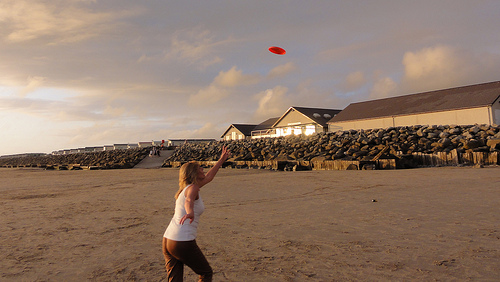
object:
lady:
[151, 147, 228, 280]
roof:
[330, 82, 497, 120]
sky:
[7, 1, 282, 111]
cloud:
[190, 67, 246, 112]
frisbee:
[268, 47, 286, 55]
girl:
[162, 142, 232, 282]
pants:
[160, 240, 213, 280]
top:
[163, 185, 206, 235]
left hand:
[221, 145, 231, 159]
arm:
[204, 145, 230, 184]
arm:
[181, 180, 199, 223]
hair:
[176, 160, 203, 195]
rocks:
[435, 127, 491, 151]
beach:
[0, 170, 500, 281]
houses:
[167, 139, 220, 145]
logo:
[271, 46, 278, 49]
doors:
[231, 132, 237, 141]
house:
[219, 122, 250, 141]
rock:
[371, 199, 378, 202]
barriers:
[182, 151, 494, 167]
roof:
[237, 124, 252, 133]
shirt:
[159, 185, 203, 240]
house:
[256, 106, 331, 134]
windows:
[283, 128, 288, 134]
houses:
[326, 101, 360, 131]